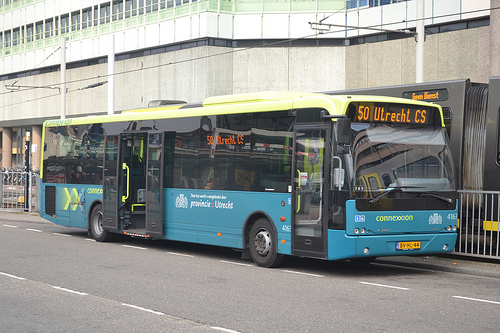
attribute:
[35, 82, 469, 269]
bus — blue, yellow, dutch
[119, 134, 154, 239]
door — ajar, open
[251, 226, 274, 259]
rim — silver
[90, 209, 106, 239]
rim — silver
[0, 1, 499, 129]
building — concrete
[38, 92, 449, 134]
roof — yellow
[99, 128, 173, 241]
rear doors — open